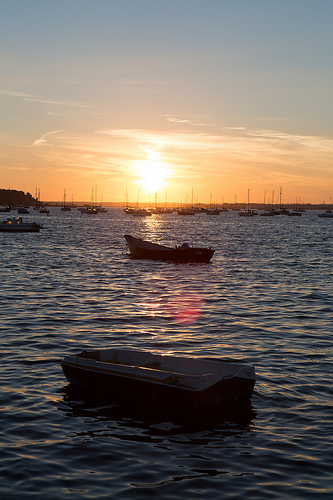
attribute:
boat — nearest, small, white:
[60, 348, 257, 411]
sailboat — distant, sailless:
[60, 187, 72, 212]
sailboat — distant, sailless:
[124, 187, 136, 214]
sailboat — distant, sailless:
[176, 192, 194, 215]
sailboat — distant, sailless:
[236, 189, 258, 217]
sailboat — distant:
[273, 185, 287, 214]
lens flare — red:
[160, 291, 204, 325]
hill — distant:
[0, 187, 44, 205]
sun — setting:
[124, 151, 177, 195]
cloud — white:
[93, 129, 332, 170]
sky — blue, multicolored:
[0, 0, 332, 205]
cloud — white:
[165, 116, 205, 126]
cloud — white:
[219, 125, 246, 134]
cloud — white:
[30, 129, 63, 147]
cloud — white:
[23, 97, 93, 108]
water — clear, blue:
[0, 205, 332, 499]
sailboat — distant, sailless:
[132, 187, 153, 216]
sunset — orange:
[0, 127, 332, 206]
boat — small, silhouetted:
[124, 234, 214, 263]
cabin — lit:
[4, 216, 23, 224]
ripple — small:
[132, 473, 229, 492]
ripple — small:
[4, 451, 81, 474]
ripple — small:
[8, 423, 52, 435]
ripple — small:
[264, 441, 311, 451]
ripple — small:
[287, 415, 315, 424]